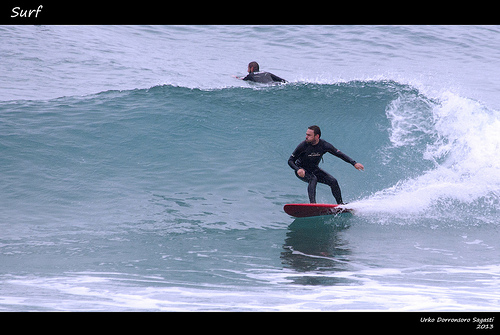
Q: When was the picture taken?
A: 2013.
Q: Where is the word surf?
A: Top left.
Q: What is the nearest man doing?
A: Surfing.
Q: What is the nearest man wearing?
A: A wetsuit.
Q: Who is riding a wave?
A: The surfer.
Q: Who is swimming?
A: The far man.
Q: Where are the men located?
A: In the ocean.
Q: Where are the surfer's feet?
A: On the surfboard.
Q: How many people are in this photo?
A: Two.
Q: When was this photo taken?
A: Daytime.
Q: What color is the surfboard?
A: Red.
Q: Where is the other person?
A: In the water.